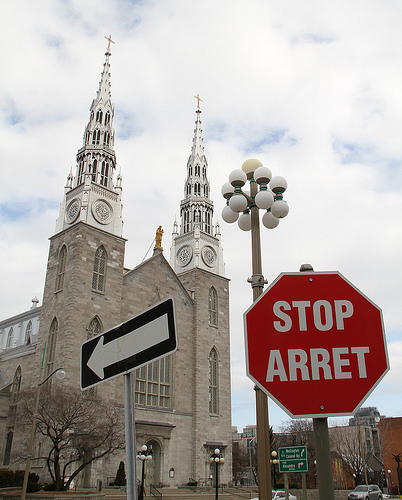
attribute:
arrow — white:
[60, 295, 186, 387]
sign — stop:
[223, 274, 398, 429]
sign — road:
[70, 281, 180, 367]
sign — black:
[79, 291, 180, 395]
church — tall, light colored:
[2, 20, 252, 498]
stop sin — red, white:
[235, 269, 390, 415]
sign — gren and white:
[231, 266, 398, 418]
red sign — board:
[242, 268, 391, 419]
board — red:
[243, 270, 390, 417]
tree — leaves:
[16, 381, 139, 472]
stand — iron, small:
[232, 225, 280, 489]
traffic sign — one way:
[62, 293, 196, 390]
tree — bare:
[6, 389, 135, 494]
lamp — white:
[35, 363, 69, 400]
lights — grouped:
[204, 137, 318, 249]